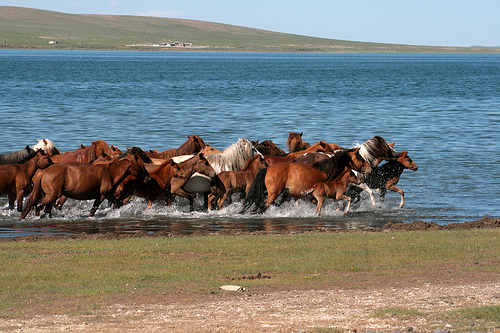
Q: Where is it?
A: This is at the beach.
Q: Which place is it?
A: It is a beach.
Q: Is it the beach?
A: Yes, it is the beach.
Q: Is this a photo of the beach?
A: Yes, it is showing the beach.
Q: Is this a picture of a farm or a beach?
A: It is showing a beach.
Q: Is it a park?
A: No, it is a beach.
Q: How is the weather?
A: It is clear.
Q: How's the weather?
A: It is clear.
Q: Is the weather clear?
A: Yes, it is clear.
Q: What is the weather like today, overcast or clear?
A: It is clear.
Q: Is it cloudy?
A: No, it is clear.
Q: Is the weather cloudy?
A: No, it is clear.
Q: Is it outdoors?
A: Yes, it is outdoors.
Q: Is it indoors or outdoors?
A: It is outdoors.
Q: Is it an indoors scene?
A: No, it is outdoors.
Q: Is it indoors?
A: No, it is outdoors.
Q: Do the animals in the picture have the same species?
A: Yes, all the animals are horses.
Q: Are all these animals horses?
A: Yes, all the animals are horses.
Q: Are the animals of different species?
A: No, all the animals are horses.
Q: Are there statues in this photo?
A: No, there are no statues.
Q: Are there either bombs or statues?
A: No, there are no statues or bombs.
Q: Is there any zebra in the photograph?
A: No, there are no zebras.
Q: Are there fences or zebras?
A: No, there are no zebras or fences.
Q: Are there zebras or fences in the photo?
A: No, there are no zebras or fences.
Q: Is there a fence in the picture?
A: No, there are no fences.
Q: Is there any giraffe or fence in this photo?
A: No, there are no fences or giraffes.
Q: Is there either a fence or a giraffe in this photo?
A: No, there are no fences or giraffes.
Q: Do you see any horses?
A: Yes, there are horses.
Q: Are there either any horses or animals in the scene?
A: Yes, there are horses.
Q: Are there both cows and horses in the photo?
A: No, there are horses but no cows.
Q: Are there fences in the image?
A: No, there are no fences.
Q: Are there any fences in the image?
A: No, there are no fences.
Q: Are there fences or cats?
A: No, there are no fences or cats.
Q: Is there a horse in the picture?
A: Yes, there is a horse.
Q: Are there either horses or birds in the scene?
A: Yes, there is a horse.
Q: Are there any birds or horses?
A: Yes, there is a horse.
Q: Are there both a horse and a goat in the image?
A: No, there is a horse but no goats.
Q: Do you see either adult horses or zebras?
A: Yes, there is an adult horse.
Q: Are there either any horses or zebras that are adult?
A: Yes, the horse is adult.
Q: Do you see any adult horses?
A: Yes, there is an adult horse.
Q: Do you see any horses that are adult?
A: Yes, there is a horse that is adult.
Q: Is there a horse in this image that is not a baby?
A: Yes, there is a adult horse.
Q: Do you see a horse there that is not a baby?
A: Yes, there is a adult horse.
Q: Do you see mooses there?
A: No, there are no mooses.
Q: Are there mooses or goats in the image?
A: No, there are no mooses or goats.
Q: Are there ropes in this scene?
A: No, there are no ropes.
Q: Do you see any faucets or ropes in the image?
A: No, there are no ropes or faucets.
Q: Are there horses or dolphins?
A: Yes, there is a horse.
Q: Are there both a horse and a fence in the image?
A: No, there is a horse but no fences.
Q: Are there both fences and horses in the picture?
A: No, there is a horse but no fences.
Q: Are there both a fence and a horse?
A: No, there is a horse but no fences.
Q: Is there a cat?
A: No, there are no cats.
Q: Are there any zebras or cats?
A: No, there are no cats or zebras.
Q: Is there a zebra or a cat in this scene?
A: No, there are no cats or zebras.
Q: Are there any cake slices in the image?
A: No, there are no cake slices.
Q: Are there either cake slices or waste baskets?
A: No, there are no cake slices or waste baskets.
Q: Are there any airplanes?
A: No, there are no airplanes.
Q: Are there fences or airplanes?
A: No, there are no airplanes or fences.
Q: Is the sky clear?
A: Yes, the sky is clear.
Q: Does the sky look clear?
A: Yes, the sky is clear.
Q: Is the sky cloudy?
A: No, the sky is clear.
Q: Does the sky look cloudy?
A: No, the sky is clear.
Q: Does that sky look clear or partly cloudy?
A: The sky is clear.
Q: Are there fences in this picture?
A: No, there are no fences.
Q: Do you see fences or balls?
A: No, there are no fences or balls.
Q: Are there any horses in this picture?
A: Yes, there is a horse.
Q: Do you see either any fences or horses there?
A: Yes, there is a horse.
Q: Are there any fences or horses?
A: Yes, there is a horse.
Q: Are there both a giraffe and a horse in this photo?
A: No, there is a horse but no giraffes.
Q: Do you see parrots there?
A: No, there are no parrots.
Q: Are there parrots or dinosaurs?
A: No, there are no parrots or dinosaurs.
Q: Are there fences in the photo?
A: No, there are no fences.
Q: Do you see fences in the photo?
A: No, there are no fences.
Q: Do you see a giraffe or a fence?
A: No, there are no fences or giraffes.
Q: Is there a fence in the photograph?
A: No, there are no fences.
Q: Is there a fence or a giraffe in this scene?
A: No, there are no fences or giraffes.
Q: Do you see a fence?
A: No, there are no fences.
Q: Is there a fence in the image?
A: No, there are no fences.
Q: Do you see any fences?
A: No, there are no fences.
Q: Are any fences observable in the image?
A: No, there are no fences.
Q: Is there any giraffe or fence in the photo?
A: No, there are no fences or giraffes.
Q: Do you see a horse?
A: Yes, there are horses.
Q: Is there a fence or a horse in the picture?
A: Yes, there are horses.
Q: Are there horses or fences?
A: Yes, there are horses.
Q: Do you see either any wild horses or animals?
A: Yes, there are wild horses.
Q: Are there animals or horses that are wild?
A: Yes, the horses are wild.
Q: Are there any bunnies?
A: No, there are no bunnies.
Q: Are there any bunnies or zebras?
A: No, there are no bunnies or zebras.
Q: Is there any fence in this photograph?
A: No, there are no fences.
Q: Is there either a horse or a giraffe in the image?
A: Yes, there is a horse.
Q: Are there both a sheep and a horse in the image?
A: No, there is a horse but no sheep.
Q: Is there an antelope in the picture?
A: No, there are no antelopes.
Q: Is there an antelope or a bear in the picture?
A: No, there are no antelopes or bears.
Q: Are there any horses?
A: Yes, there is a horse.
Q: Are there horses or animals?
A: Yes, there is a horse.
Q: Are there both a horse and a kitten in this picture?
A: No, there is a horse but no kittens.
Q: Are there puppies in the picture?
A: No, there are no puppies.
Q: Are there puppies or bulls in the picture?
A: No, there are no puppies or bulls.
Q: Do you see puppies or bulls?
A: No, there are no puppies or bulls.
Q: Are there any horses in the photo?
A: Yes, there is a horse.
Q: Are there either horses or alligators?
A: Yes, there is a horse.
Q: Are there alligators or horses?
A: Yes, there is a horse.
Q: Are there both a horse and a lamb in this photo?
A: No, there is a horse but no lambs.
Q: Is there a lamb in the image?
A: No, there are no lambs.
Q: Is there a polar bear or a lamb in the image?
A: No, there are no lambs or polar bears.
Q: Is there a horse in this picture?
A: Yes, there are horses.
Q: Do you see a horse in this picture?
A: Yes, there are horses.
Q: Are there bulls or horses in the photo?
A: Yes, there are horses.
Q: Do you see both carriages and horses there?
A: No, there are horses but no carriages.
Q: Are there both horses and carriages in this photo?
A: No, there are horses but no carriages.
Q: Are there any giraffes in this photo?
A: No, there are no giraffes.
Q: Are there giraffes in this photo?
A: No, there are no giraffes.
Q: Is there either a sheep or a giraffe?
A: No, there are no giraffes or sheep.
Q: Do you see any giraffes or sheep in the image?
A: No, there are no giraffes or sheep.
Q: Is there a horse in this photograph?
A: Yes, there is a horse.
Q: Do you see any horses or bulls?
A: Yes, there is a horse.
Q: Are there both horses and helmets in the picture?
A: No, there is a horse but no helmets.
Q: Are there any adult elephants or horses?
A: Yes, there is an adult horse.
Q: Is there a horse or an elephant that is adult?
A: Yes, the horse is adult.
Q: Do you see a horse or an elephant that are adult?
A: Yes, the horse is adult.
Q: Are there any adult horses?
A: Yes, there is an adult horse.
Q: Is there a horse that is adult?
A: Yes, there is a horse that is adult.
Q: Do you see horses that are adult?
A: Yes, there is a horse that is adult.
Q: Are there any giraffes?
A: No, there are no giraffes.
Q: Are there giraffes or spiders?
A: No, there are no giraffes or spiders.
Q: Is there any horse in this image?
A: Yes, there is a horse.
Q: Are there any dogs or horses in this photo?
A: Yes, there is a horse.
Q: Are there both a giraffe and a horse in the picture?
A: No, there is a horse but no giraffes.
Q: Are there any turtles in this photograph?
A: No, there are no turtles.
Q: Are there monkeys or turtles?
A: No, there are no turtles or monkeys.